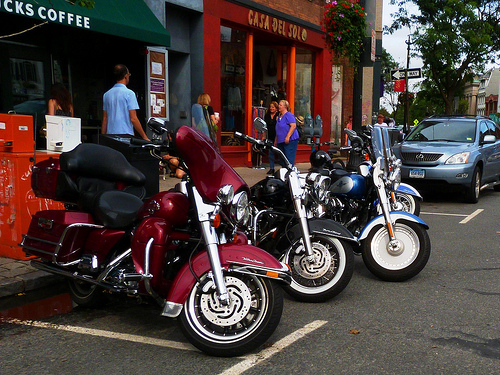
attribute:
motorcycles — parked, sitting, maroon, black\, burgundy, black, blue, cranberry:
[91, 206, 377, 253]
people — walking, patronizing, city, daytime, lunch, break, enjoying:
[79, 89, 299, 135]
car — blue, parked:
[416, 115, 488, 146]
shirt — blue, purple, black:
[107, 93, 141, 108]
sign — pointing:
[386, 64, 423, 79]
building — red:
[191, 28, 232, 59]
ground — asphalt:
[359, 296, 404, 312]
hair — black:
[106, 70, 122, 75]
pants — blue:
[283, 148, 299, 152]